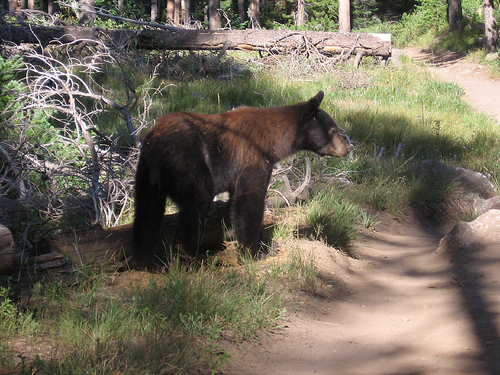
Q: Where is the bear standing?
A: In the grass.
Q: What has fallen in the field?
A: A tree.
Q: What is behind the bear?
A: Dead branches.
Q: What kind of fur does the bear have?
A: Dark brown long fur.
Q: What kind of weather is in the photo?
A: Sunny.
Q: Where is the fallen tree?
A: In the grass beside the path.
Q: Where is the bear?
A: In the woods.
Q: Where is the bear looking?
A: To the right.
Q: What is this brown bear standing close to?
A: A Road.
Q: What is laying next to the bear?
A: Tree limbs.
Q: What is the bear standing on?
A: Grass.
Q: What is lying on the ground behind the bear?
A: Tree trunk.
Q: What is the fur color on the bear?
A: Brown.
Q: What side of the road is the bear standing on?
A: Left.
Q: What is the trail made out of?
A: Dirt.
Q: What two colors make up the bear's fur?
A: Brown and black.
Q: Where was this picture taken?
A: In the forest.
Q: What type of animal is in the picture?
A: A bear.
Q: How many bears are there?
A: One.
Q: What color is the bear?
A: Brown.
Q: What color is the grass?
A: Green.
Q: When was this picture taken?
A: During the day.